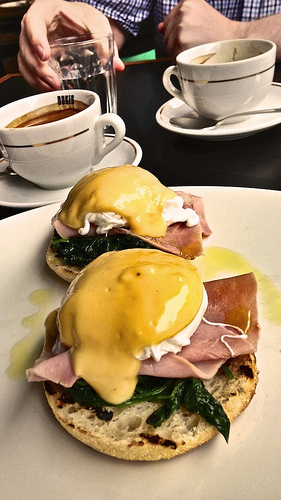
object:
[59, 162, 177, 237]
cheese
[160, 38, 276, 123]
teacup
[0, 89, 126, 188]
teacup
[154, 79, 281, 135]
plate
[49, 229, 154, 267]
leaf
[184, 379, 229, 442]
leaf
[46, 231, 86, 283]
english muffin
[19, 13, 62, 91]
fingers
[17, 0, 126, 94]
hand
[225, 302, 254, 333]
sauce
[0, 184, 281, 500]
plate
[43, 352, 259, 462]
bun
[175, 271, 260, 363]
meat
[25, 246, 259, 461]
burger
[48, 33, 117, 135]
glass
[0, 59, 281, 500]
table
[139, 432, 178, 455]
part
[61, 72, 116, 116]
liquid